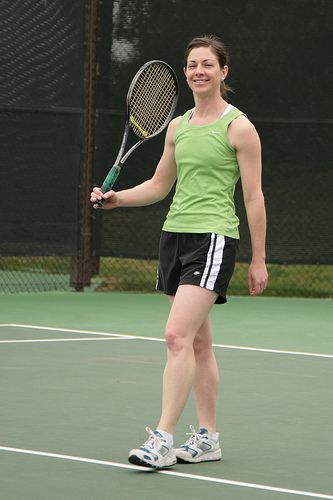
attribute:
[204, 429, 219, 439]
socks — white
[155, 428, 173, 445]
socks — white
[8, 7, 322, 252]
fence — chain link, tall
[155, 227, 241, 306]
shorts — black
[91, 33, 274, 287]
woman — pictured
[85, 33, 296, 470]
woman — tennis-playing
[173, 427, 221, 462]
shoe — tennis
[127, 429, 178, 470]
shoe — tennis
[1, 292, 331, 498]
court — tennis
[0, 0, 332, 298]
fence — pictured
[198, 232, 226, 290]
line — white